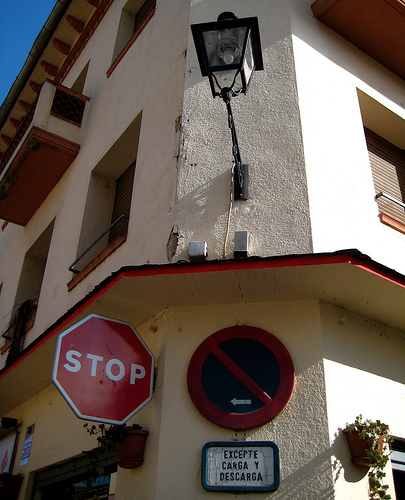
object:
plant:
[81, 421, 144, 453]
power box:
[233, 229, 249, 257]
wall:
[174, 173, 212, 224]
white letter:
[63, 350, 83, 373]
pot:
[116, 430, 149, 470]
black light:
[188, 11, 264, 200]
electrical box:
[188, 241, 207, 257]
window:
[354, 87, 405, 235]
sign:
[198, 434, 283, 498]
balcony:
[64, 213, 130, 288]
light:
[188, 8, 265, 100]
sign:
[187, 323, 296, 431]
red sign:
[52, 313, 156, 428]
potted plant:
[339, 411, 391, 498]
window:
[67, 110, 141, 290]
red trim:
[1, 247, 403, 377]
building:
[0, 0, 405, 498]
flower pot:
[343, 414, 394, 467]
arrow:
[231, 397, 252, 407]